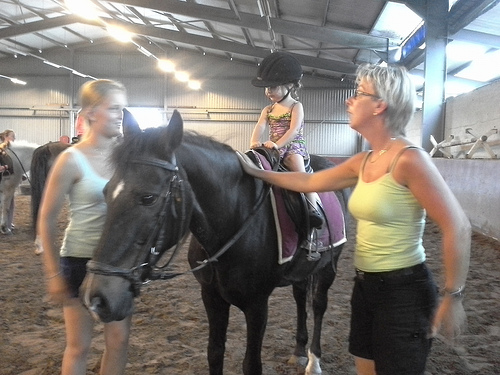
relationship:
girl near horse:
[37, 75, 132, 373] [82, 104, 380, 374]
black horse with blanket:
[85, 107, 351, 375] [247, 146, 350, 265]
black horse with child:
[85, 107, 351, 375] [249, 50, 321, 223]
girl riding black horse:
[248, 50, 326, 229] [85, 107, 351, 375]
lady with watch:
[232, 60, 475, 375] [441, 288, 469, 300]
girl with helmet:
[248, 50, 326, 229] [247, 43, 304, 85]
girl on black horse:
[248, 50, 326, 229] [85, 107, 351, 375]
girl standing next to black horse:
[37, 75, 132, 373] [85, 107, 351, 375]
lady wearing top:
[232, 60, 475, 375] [346, 147, 430, 273]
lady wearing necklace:
[292, 60, 472, 358] [364, 128, 418, 168]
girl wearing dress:
[248, 50, 326, 229] [263, 100, 310, 169]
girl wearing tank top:
[37, 75, 132, 373] [60, 140, 124, 258]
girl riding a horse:
[248, 50, 326, 229] [10, 65, 398, 312]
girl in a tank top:
[37, 76, 132, 375] [58, 140, 113, 260]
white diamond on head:
[108, 176, 132, 209] [68, 110, 211, 334]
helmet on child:
[248, 49, 312, 91] [239, 38, 335, 232]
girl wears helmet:
[249, 45, 326, 152] [246, 44, 304, 89]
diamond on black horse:
[106, 174, 127, 199] [85, 107, 351, 375]